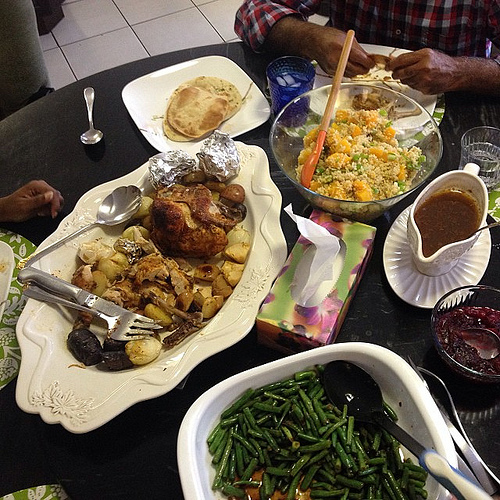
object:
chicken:
[152, 181, 238, 261]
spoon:
[24, 185, 143, 270]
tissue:
[254, 205, 377, 355]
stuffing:
[295, 106, 427, 219]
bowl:
[269, 82, 443, 221]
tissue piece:
[284, 202, 347, 307]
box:
[255, 202, 376, 354]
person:
[233, 0, 500, 97]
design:
[29, 380, 95, 427]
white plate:
[15, 137, 287, 434]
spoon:
[80, 87, 104, 145]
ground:
[440, 161, 462, 196]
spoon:
[205, 361, 430, 500]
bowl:
[174, 341, 459, 500]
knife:
[17, 266, 163, 330]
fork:
[18, 280, 161, 341]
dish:
[15, 139, 286, 433]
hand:
[0, 179, 67, 227]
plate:
[97, 40, 268, 102]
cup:
[431, 285, 500, 381]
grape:
[432, 305, 500, 382]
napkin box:
[254, 208, 377, 360]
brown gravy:
[413, 186, 482, 259]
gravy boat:
[407, 161, 490, 276]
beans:
[205, 363, 433, 500]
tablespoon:
[299, 30, 354, 189]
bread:
[120, 54, 270, 159]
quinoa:
[295, 105, 426, 223]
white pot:
[176, 341, 460, 500]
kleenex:
[282, 201, 346, 308]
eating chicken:
[67, 171, 250, 373]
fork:
[108, 313, 164, 341]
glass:
[265, 56, 315, 128]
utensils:
[21, 184, 142, 270]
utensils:
[23, 284, 163, 339]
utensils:
[323, 359, 496, 500]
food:
[67, 130, 249, 370]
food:
[295, 107, 427, 225]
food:
[162, 76, 242, 142]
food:
[205, 359, 430, 500]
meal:
[67, 46, 499, 500]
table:
[0, 37, 500, 500]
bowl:
[407, 162, 488, 276]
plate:
[14, 138, 289, 434]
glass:
[458, 126, 500, 190]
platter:
[120, 56, 270, 157]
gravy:
[412, 186, 479, 259]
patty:
[163, 74, 242, 142]